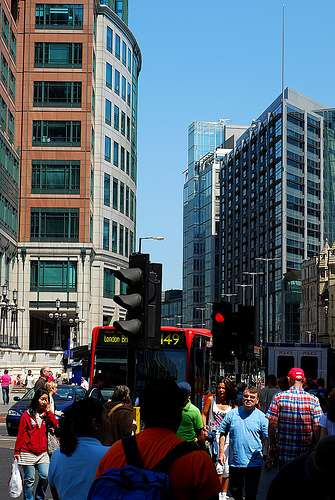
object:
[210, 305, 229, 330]
stoplight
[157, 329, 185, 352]
149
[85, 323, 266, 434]
bus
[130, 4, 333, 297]
sky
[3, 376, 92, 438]
car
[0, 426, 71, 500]
street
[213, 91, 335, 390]
building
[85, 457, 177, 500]
backpack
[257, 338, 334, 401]
van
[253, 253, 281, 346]
street light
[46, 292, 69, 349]
street light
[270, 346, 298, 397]
door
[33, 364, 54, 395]
man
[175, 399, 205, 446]
shirt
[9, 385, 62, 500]
woman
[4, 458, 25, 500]
bag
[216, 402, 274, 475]
shirt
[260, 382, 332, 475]
shirt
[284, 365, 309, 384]
hat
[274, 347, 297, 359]
police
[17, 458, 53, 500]
jeans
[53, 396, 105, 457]
hair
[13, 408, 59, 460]
jacket